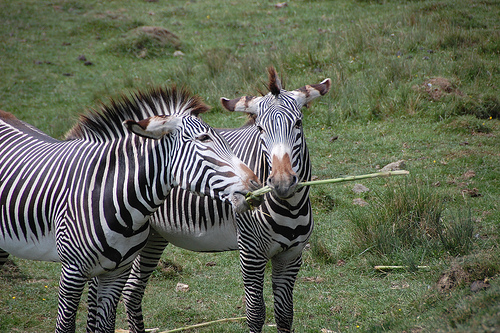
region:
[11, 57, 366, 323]
there are two zebras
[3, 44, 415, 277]
the two zebras are black an white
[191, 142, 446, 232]
the two zebras are fighting over a branch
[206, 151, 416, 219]
the two zebras are both biting on a branch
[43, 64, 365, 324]
the two zebras are both standing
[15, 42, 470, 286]
the two zebras are in a field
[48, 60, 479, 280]
the two zebras are in the wild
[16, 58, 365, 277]
the two zebras are well fed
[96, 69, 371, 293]
the two zebras are pulling on a stick in opposite directions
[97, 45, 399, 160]
the two zebras have their ears pulled back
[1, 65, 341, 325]
two Zebras stand next to eachother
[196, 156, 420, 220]
the two zebras share a plant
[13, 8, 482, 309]
the ground is covered in green grass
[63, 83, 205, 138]
the zebra has a short mane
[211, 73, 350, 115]
the zebras ears are pointed off to the sides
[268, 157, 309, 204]
the zebra holds the plant in its mouth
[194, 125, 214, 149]
one of the zebras eyes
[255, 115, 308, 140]
both eyes are open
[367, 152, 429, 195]
a rock in the pasture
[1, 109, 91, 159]
a black stripe goes down the zebras back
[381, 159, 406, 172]
A rock on the ground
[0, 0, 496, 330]
Grass beneath the zebras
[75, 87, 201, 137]
The mane of the zebra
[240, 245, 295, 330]
The front legs of the zebra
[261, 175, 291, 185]
The nose of the zebra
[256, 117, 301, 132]
The eyes of the zebra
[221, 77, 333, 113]
The ears of the zebra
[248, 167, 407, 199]
A plant in the zebras' mouths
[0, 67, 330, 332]
The zebras are eating a plant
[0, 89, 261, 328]
The zebra has black and white stripes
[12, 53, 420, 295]
Two zebras chewing on the same branch.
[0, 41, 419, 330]
two zebra share a chew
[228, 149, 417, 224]
pass the long reedy stick of tall grass on the left hand side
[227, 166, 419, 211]
could almost be green bamboo; if so, they're in a park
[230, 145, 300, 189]
rusty brown top noses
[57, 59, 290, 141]
mohican-styled long manes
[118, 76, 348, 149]
three visible ears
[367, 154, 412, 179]
a rock behind the grass pipe which almost looks balanced upon it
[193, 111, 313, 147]
2 1/2 visible dark, thoughtful eyes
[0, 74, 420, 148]
fine brown detailing @ tops of ears & manes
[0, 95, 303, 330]
thin stripes + long dark stripe down back make these grevy's zebras